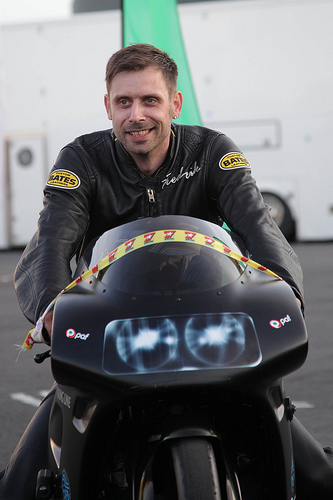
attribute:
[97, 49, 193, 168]
face — smiling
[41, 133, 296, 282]
coat — black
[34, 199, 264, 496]
bike — branded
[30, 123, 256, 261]
jacket — leather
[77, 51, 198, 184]
man — smiling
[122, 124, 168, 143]
teeth — yellow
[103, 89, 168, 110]
eyes — blue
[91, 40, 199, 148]
man — brown haired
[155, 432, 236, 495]
tire — black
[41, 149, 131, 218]
jacket — yellow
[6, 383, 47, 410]
line — white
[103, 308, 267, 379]
headlights — strange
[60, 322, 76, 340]
logo — red, white, green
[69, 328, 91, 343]
logo — green, white, red, round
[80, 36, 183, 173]
dude — goofy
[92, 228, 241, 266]
ribbon — yellow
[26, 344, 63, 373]
gear — round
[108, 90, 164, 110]
eyes — blue green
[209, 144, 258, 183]
patches — yellow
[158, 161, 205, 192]
writing — white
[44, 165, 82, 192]
patch — yellow, black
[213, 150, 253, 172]
patch — yellow, black